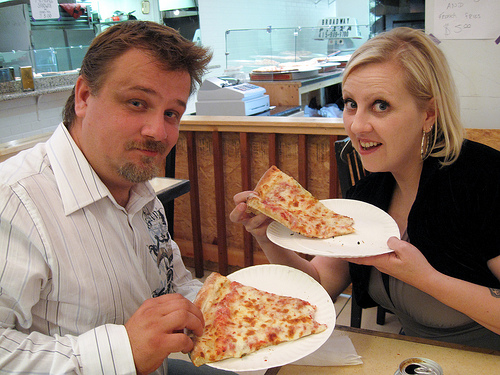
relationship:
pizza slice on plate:
[246, 163, 352, 241] [265, 196, 399, 261]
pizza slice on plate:
[185, 269, 327, 370] [183, 260, 336, 374]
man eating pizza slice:
[1, 16, 217, 373] [185, 269, 327, 370]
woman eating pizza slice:
[226, 26, 496, 348] [246, 163, 352, 241]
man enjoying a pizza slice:
[1, 16, 217, 373] [185, 269, 327, 370]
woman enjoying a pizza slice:
[226, 26, 496, 348] [246, 163, 352, 241]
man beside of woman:
[1, 16, 217, 373] [226, 26, 496, 348]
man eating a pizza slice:
[1, 16, 217, 373] [185, 269, 327, 370]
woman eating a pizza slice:
[226, 26, 496, 348] [246, 163, 352, 241]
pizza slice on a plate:
[246, 163, 352, 241] [265, 196, 399, 261]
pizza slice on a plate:
[185, 269, 327, 370] [183, 260, 336, 374]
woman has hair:
[226, 26, 496, 348] [340, 26, 466, 167]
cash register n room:
[195, 74, 269, 118] [3, 2, 496, 374]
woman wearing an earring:
[226, 26, 496, 348] [419, 128, 431, 156]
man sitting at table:
[1, 16, 217, 373] [265, 324, 498, 374]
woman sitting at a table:
[226, 26, 496, 348] [265, 324, 498, 374]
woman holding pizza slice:
[226, 26, 496, 348] [246, 163, 352, 241]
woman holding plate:
[226, 26, 496, 348] [265, 196, 399, 261]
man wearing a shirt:
[1, 16, 217, 373] [3, 121, 206, 373]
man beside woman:
[1, 16, 217, 373] [226, 26, 496, 348]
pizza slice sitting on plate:
[246, 163, 352, 241] [265, 196, 399, 261]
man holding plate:
[1, 16, 217, 373] [183, 260, 336, 374]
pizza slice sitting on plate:
[185, 269, 327, 370] [183, 260, 336, 374]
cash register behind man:
[195, 74, 269, 118] [1, 16, 217, 373]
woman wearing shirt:
[226, 26, 496, 348] [332, 137, 499, 346]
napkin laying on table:
[296, 332, 363, 368] [265, 324, 498, 374]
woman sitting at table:
[226, 26, 496, 348] [265, 324, 498, 374]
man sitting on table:
[1, 16, 217, 373] [265, 324, 498, 374]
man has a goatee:
[1, 16, 217, 373] [111, 156, 158, 181]